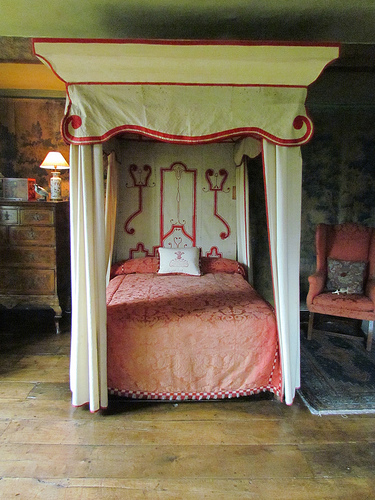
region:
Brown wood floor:
[30, 405, 218, 477]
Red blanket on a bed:
[109, 257, 324, 418]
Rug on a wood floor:
[290, 345, 374, 416]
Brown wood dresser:
[1, 203, 92, 339]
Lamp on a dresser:
[31, 139, 100, 238]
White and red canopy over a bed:
[19, 93, 309, 403]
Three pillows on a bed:
[115, 240, 266, 285]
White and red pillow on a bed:
[141, 239, 217, 306]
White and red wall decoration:
[111, 156, 277, 277]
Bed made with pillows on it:
[107, 244, 322, 404]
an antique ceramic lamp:
[36, 146, 74, 202]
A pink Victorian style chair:
[302, 211, 372, 358]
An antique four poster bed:
[64, 105, 307, 415]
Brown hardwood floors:
[11, 406, 374, 499]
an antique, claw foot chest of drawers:
[0, 194, 69, 347]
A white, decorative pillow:
[151, 242, 206, 280]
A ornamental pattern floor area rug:
[268, 294, 373, 421]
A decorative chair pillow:
[319, 254, 369, 300]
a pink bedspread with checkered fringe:
[95, 251, 285, 406]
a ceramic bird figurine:
[28, 180, 51, 201]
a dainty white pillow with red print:
[152, 243, 206, 278]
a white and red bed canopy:
[29, 33, 345, 423]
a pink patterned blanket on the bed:
[96, 248, 288, 410]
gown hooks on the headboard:
[112, 162, 245, 195]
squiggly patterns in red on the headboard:
[115, 155, 247, 272]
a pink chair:
[302, 217, 373, 341]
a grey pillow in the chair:
[320, 256, 369, 296]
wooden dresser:
[0, 195, 73, 336]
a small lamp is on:
[39, 148, 72, 201]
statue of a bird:
[28, 181, 54, 208]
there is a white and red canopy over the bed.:
[62, 39, 337, 419]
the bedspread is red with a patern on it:
[88, 247, 288, 403]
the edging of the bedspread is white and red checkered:
[106, 342, 283, 403]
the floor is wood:
[3, 307, 364, 494]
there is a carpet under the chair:
[289, 317, 374, 428]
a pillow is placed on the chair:
[308, 214, 373, 358]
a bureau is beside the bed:
[0, 178, 66, 330]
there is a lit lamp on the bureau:
[43, 147, 66, 199]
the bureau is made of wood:
[5, 188, 69, 336]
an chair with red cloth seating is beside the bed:
[302, 213, 372, 355]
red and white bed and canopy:
[30, 36, 336, 405]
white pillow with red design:
[157, 246, 200, 276]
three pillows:
[112, 245, 241, 277]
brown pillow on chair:
[325, 256, 366, 298]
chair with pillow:
[304, 220, 374, 348]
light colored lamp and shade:
[38, 150, 69, 199]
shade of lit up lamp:
[38, 150, 66, 169]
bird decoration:
[31, 181, 46, 198]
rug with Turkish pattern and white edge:
[296, 323, 372, 414]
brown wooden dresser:
[1, 197, 69, 334]